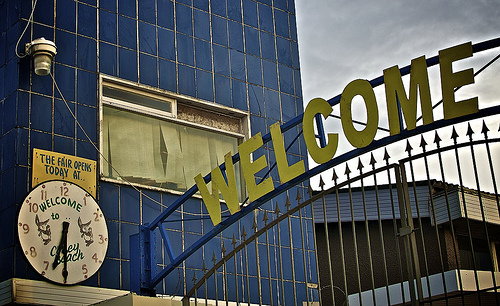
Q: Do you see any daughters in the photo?
A: No, there are no daughters.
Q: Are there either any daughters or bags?
A: No, there are no daughters or bags.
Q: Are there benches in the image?
A: No, there are no benches.